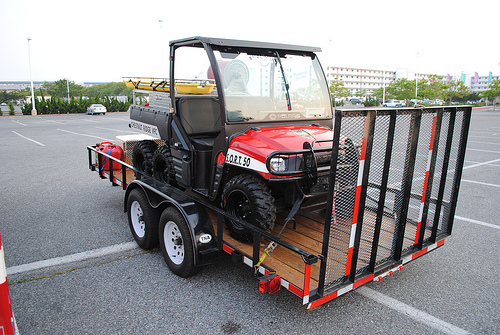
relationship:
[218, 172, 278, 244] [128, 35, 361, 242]
black tire on vehicle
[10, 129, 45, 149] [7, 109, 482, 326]
line in parking lot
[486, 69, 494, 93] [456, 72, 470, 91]
flag in pole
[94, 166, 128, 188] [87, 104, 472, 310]
hazard tape on trailer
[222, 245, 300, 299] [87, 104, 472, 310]
hazard tape on trailer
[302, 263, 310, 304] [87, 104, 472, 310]
hazard tape on trailer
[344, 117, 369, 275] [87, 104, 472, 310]
hazard tape on trailer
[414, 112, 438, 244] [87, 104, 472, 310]
hazard tape on trailer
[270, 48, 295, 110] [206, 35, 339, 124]
wiper on windshield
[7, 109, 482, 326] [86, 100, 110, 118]
parking lot containing vehicle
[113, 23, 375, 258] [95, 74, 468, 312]
vehicle on trailer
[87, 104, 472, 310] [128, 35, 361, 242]
trailer under vehicle